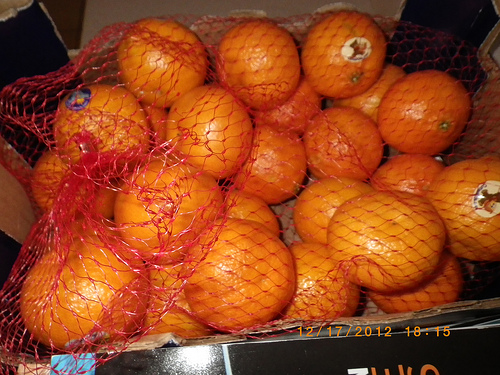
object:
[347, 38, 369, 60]
sticker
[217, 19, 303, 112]
orange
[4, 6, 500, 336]
bag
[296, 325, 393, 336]
date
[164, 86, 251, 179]
oranges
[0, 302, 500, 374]
box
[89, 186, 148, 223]
hole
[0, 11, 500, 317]
netting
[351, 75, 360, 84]
stem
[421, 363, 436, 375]
letters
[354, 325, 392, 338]
2012